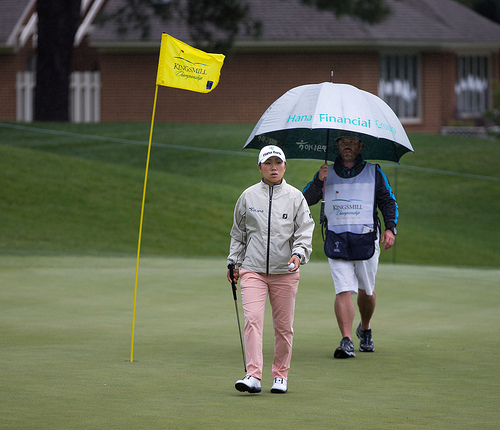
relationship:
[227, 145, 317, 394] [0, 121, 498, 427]
woman on course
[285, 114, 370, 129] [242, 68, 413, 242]
word on umbrella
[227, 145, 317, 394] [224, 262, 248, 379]
woman holding club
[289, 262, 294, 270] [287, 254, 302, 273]
ball in hand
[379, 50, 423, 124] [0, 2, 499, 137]
window on building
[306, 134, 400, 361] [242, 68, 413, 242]
man with umbrella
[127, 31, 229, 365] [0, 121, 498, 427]
flag on course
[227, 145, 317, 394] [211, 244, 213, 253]
woman on grass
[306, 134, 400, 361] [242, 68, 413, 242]
man holding umbrella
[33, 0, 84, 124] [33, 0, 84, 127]
tree has tree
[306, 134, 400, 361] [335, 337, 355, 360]
man has shoe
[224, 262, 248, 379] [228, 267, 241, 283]
club in hand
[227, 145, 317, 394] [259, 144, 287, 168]
woman wearing hat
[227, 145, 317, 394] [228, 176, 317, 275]
woman wearing jacket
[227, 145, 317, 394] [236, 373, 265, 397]
woman wearing shoe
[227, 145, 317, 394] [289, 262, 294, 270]
woman holding ball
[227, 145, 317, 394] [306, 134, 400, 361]
woman with man